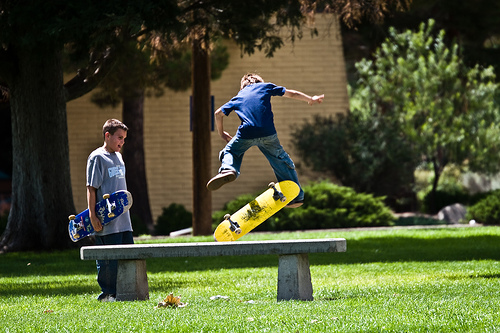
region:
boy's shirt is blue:
[212, 81, 298, 160]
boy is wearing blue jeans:
[207, 123, 297, 192]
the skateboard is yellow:
[185, 177, 312, 253]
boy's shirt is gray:
[71, 141, 138, 238]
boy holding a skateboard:
[52, 96, 152, 287]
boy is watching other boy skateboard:
[41, 35, 353, 331]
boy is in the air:
[173, 41, 318, 254]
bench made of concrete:
[50, 215, 360, 310]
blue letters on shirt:
[85, 158, 135, 182]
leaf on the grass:
[141, 284, 186, 326]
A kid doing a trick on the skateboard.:
[203, 75, 320, 227]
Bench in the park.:
[74, 230, 361, 317]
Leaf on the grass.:
[149, 278, 208, 321]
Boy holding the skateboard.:
[55, 142, 149, 226]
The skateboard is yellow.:
[209, 165, 301, 237]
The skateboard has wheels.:
[98, 187, 117, 226]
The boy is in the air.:
[180, 62, 322, 212]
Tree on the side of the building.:
[293, 40, 479, 207]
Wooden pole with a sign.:
[176, 30, 228, 232]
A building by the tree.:
[146, 33, 360, 221]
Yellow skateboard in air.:
[210, 179, 302, 241]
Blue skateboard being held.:
[62, 185, 134, 246]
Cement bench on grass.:
[75, 231, 352, 306]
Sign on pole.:
[183, 93, 217, 133]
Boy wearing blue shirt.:
[211, 73, 313, 203]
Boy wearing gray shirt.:
[81, 116, 139, 283]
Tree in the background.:
[349, 17, 493, 216]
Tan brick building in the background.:
[67, 5, 354, 237]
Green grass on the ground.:
[1, 233, 498, 332]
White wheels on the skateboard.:
[62, 192, 118, 240]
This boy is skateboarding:
[205, 69, 327, 241]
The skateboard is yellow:
[210, 179, 302, 242]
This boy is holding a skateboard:
[66, 117, 137, 302]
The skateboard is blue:
[66, 188, 133, 243]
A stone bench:
[79, 235, 351, 302]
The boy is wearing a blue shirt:
[212, 70, 327, 139]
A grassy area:
[3, 227, 498, 332]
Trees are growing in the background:
[1, 2, 497, 253]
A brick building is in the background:
[1, 10, 359, 227]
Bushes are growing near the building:
[156, 182, 400, 231]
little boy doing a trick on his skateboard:
[187, 55, 340, 251]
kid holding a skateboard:
[67, 113, 172, 298]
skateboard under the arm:
[54, 188, 138, 241]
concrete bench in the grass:
[75, 236, 365, 307]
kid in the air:
[198, 68, 321, 208]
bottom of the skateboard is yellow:
[203, 179, 308, 241]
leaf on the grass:
[154, 290, 184, 312]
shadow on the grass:
[444, 266, 499, 281]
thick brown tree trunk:
[1, 52, 99, 256]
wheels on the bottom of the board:
[98, 192, 118, 222]